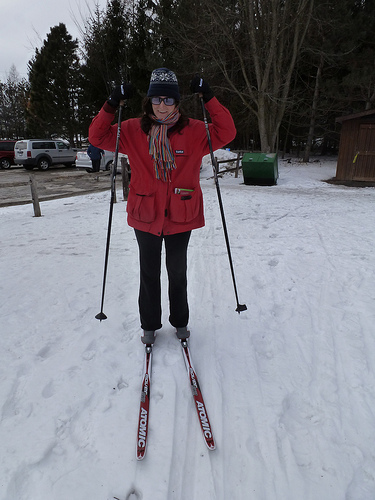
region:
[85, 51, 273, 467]
female skiier in the snow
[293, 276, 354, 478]
white snow on the ground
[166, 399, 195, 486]
tracks in the snow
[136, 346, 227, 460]
skiis of a woman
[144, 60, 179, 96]
hat on a woman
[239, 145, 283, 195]
trash bin in the snow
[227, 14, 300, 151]
trunk of a tree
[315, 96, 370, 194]
shed in the snow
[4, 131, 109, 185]
cars in a parking lot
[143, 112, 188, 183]
scarf of a woman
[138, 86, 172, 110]
sunglasses on the face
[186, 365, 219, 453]
name of ski company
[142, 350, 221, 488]
two red and black skis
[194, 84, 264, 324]
left hand holding ski upwards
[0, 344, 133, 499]
snow markings in the snow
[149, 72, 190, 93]
white and gray cap on head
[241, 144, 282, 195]
green box in the back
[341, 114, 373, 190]
brown wooden shed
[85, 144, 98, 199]
person walking toward the car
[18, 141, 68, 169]
white car is parked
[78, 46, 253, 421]
female skier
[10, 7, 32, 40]
white clouds in blue sky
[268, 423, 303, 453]
white snow on hill side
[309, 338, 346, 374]
white snow on hill side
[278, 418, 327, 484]
white snow on hill side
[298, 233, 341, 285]
white snow on hill side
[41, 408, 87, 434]
white snow on hill side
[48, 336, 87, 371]
white snow on hill side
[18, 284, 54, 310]
white snow on hill side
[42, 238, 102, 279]
white snow on hill side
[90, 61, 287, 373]
woman is skiing on snow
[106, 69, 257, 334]
woman is skiing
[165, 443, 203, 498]
tracks from ski can be seen on snow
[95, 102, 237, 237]
woman wearing a red coat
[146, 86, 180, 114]
woman wearing glasses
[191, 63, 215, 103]
woman wearing black glove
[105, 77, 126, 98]
woman wearing black glove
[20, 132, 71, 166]
parked vehicle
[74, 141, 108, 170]
park vehicle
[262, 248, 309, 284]
white snow on hill side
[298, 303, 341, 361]
white snow on hill side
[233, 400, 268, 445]
white snow on hill side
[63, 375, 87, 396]
white snow on hill side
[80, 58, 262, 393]
woman skier with red jacket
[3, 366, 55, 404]
white snow on hill side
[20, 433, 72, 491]
white snow on hill side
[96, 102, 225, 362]
A woman in a red jacket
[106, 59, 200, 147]
A lady with gray hat on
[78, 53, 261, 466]
A person is skiing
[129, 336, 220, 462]
A pair of skis on the snow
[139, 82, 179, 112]
A pair of goggles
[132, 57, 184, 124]
Knit hat on person's head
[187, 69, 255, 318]
A black ski pole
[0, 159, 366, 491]
Ski tracks on the white snow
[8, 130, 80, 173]
A jeep is white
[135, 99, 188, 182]
A scarf around a neck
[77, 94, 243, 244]
A jacket is red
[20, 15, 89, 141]
A tall pine tree